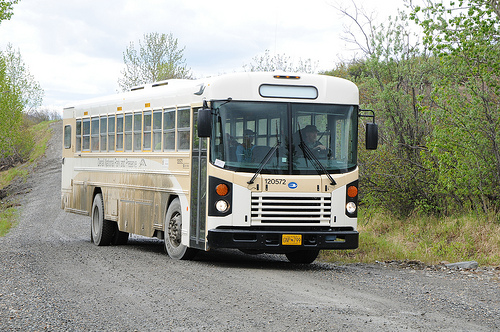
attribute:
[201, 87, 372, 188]
window — two pane, very large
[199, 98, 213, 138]
mirror — black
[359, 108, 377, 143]
mirror — black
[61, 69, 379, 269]
bus — white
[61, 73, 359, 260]
bus — white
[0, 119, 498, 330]
road — gravel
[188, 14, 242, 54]
sky — blue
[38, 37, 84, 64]
sky — partly cloudy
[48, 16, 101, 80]
sky — blue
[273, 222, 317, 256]
license plate — yellow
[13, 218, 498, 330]
road — gravel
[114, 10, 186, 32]
clouds — white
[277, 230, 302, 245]
license plate — yellow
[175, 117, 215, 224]
double doors — black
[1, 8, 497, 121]
clouds — white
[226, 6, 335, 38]
cloud — white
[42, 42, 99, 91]
cloud — white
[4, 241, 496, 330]
road — dark gray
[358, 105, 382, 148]
mirror — black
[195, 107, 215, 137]
mirror — black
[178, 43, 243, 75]
sky — blue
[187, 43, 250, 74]
sky — blue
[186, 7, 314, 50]
clouds — white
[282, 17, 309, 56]
clouds — white